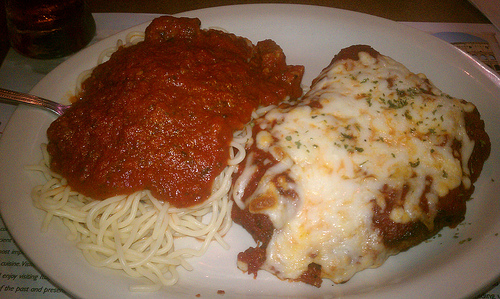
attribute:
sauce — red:
[39, 11, 310, 208]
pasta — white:
[43, 189, 220, 292]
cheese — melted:
[242, 48, 480, 292]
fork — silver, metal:
[3, 87, 71, 113]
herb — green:
[287, 76, 446, 173]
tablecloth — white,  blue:
[427, 12, 499, 69]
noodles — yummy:
[31, 10, 250, 278]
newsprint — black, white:
[2, 234, 60, 298]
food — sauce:
[119, 10, 287, 87]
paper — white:
[4, 232, 57, 294]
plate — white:
[18, 13, 498, 296]